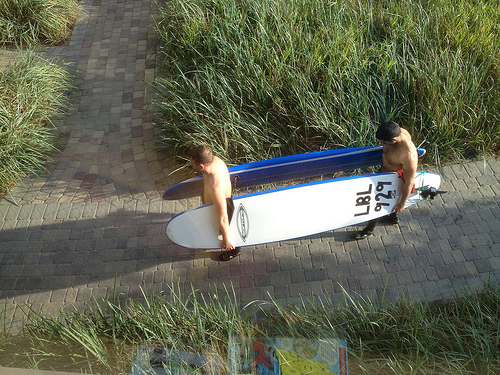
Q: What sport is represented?
A: Surfing.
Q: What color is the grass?
A: Green.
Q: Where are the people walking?
A: On sidewalk.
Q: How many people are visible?
A: Two.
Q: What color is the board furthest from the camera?
A: Blue.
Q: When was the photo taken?
A: Daytime.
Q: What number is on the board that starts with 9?
A: 929.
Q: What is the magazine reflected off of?
A: Window.